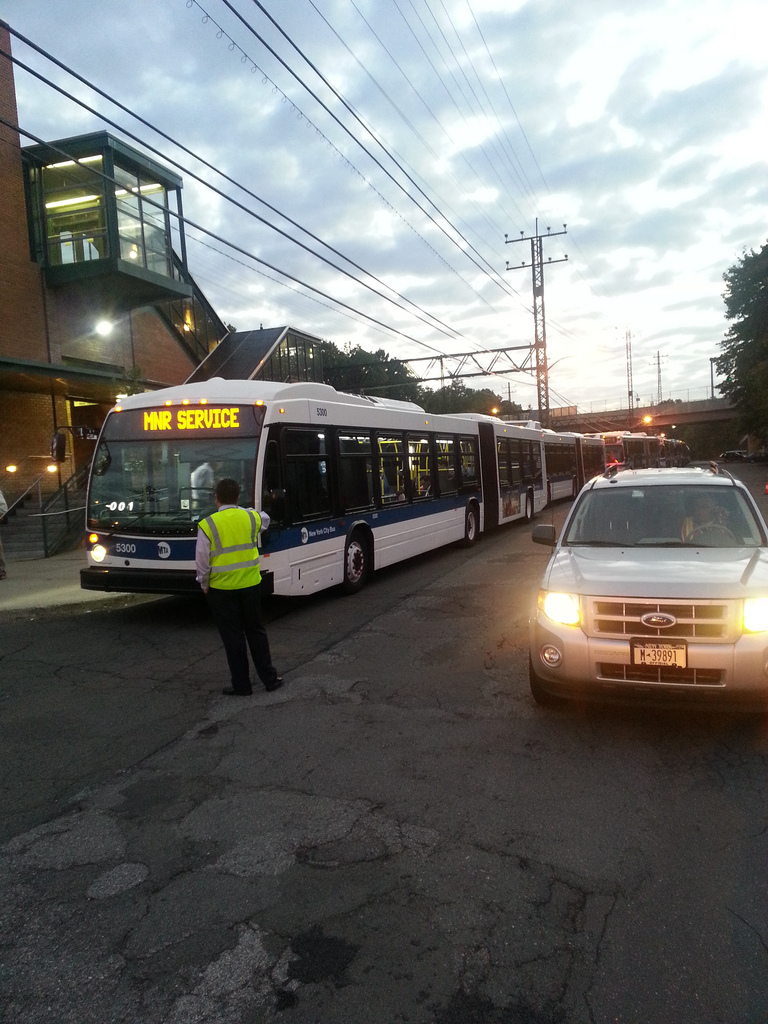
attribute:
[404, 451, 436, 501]
glass — clean, clear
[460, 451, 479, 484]
glass — clear, clean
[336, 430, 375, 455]
glass — clean, clear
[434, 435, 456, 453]
glass — clear, clean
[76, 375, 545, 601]
bus — large, white, blue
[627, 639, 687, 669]
license plate — black and white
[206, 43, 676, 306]
cloudy sky — light blue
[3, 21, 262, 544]
building — bricked 